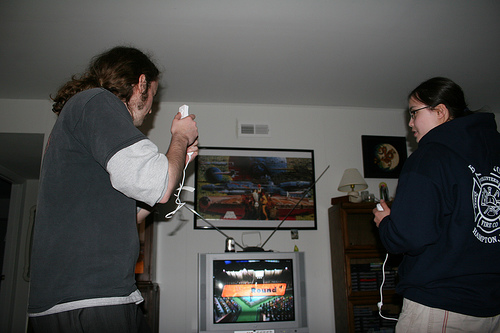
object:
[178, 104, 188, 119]
controller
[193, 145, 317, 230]
picture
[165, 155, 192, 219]
wire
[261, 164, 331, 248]
aentenna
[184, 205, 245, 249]
aentenna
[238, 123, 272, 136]
vent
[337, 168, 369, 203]
lamp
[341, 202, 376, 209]
shelf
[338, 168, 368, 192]
shade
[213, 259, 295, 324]
game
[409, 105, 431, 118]
glasses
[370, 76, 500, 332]
woman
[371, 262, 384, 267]
cd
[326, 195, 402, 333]
bookcase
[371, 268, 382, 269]
cd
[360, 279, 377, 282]
cd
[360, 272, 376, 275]
cd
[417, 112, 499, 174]
hood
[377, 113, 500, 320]
sweater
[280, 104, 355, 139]
wall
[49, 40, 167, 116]
hair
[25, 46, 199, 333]
man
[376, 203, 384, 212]
controller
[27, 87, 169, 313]
shirt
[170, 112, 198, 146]
hand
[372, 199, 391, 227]
hand